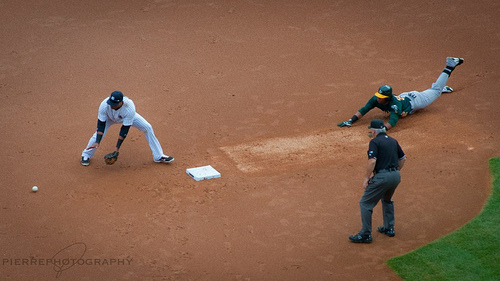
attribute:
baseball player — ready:
[73, 82, 176, 177]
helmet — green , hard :
[373, 87, 394, 98]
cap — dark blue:
[105, 91, 125, 106]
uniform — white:
[85, 94, 177, 189]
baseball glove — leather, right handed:
[102, 151, 117, 165]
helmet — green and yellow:
[370, 79, 396, 101]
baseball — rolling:
[28, 181, 41, 195]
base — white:
[186, 164, 226, 181]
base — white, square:
[183, 147, 268, 208]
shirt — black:
[366, 135, 405, 172]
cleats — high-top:
[444, 53, 466, 70]